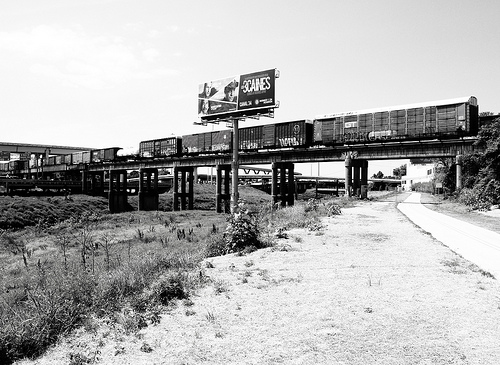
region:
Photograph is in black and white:
[0, 3, 499, 364]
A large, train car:
[297, 101, 478, 138]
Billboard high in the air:
[191, 71, 276, 121]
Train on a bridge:
[292, 91, 489, 176]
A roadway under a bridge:
[366, 130, 481, 267]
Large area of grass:
[24, 228, 145, 287]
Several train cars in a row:
[40, 130, 192, 175]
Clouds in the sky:
[10, 24, 177, 104]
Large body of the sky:
[317, 22, 464, 79]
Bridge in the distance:
[315, 170, 340, 190]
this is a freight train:
[7, 80, 495, 177]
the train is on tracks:
[10, 85, 496, 158]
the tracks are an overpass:
[15, 80, 497, 177]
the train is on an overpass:
[15, 92, 477, 166]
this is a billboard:
[170, 58, 316, 120]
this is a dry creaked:
[10, 183, 276, 258]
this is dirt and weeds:
[173, 181, 492, 362]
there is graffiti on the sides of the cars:
[126, 110, 308, 162]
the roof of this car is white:
[310, 94, 489, 119]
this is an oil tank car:
[109, 143, 153, 158]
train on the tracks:
[75, 123, 457, 149]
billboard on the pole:
[187, 65, 284, 120]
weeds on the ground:
[0, 250, 133, 327]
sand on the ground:
[270, 252, 430, 354]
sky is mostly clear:
[327, 25, 394, 86]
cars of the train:
[261, 119, 455, 144]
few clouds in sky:
[15, 24, 153, 80]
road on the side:
[405, 188, 489, 251]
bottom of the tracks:
[252, 158, 298, 218]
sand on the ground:
[82, 204, 144, 239]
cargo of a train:
[407, 98, 474, 136]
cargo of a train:
[363, 112, 424, 140]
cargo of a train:
[286, 108, 338, 142]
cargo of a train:
[239, 122, 283, 150]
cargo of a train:
[197, 133, 235, 151]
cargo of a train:
[139, 128, 190, 159]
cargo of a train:
[119, 146, 146, 161]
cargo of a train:
[97, 145, 121, 162]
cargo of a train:
[66, 143, 103, 170]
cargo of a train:
[43, 155, 74, 170]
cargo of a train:
[372, 109, 406, 150]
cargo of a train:
[336, 108, 367, 156]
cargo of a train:
[315, 121, 339, 155]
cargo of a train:
[290, 116, 318, 150]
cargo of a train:
[260, 125, 290, 150]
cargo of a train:
[209, 123, 231, 153]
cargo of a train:
[175, 122, 215, 164]